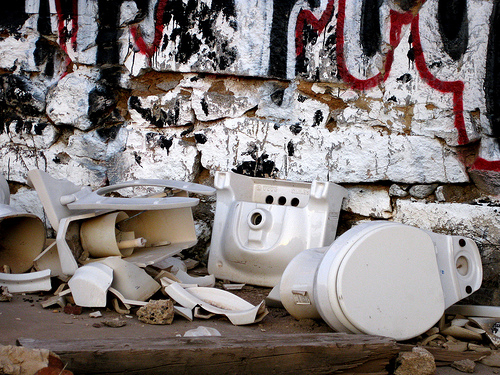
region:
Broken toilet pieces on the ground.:
[61, 253, 273, 338]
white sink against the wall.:
[209, 165, 346, 288]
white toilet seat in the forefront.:
[60, 170, 213, 213]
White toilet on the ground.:
[278, 218, 490, 345]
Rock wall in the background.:
[0, 0, 495, 298]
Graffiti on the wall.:
[31, 0, 498, 177]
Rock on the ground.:
[394, 342, 439, 374]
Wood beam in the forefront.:
[15, 331, 402, 373]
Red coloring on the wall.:
[55, 0, 498, 175]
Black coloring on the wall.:
[32, 2, 497, 182]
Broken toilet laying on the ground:
[25, 137, 239, 311]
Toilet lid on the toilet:
[331, 229, 453, 354]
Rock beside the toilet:
[130, 287, 188, 347]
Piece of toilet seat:
[174, 268, 248, 325]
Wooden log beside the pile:
[40, 320, 298, 364]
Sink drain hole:
[250, 203, 267, 230]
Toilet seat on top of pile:
[67, 165, 237, 240]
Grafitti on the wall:
[300, 20, 477, 117]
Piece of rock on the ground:
[101, 310, 139, 347]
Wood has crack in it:
[260, 340, 315, 370]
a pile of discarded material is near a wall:
[5, 136, 495, 366]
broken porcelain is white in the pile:
[3, 163, 259, 343]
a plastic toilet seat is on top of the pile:
[69, 174, 213, 211]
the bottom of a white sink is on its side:
[208, 170, 333, 295]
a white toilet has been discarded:
[278, 220, 482, 342]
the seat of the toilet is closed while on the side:
[326, 222, 450, 343]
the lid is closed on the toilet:
[335, 224, 447, 343]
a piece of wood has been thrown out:
[13, 329, 404, 374]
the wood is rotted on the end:
[323, 330, 409, 374]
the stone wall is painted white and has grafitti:
[7, 7, 496, 244]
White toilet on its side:
[283, 222, 483, 339]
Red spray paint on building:
[385, 8, 422, 73]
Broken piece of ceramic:
[67, 258, 116, 308]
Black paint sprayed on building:
[267, 0, 292, 85]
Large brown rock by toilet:
[396, 348, 436, 373]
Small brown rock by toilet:
[450, 356, 476, 373]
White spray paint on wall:
[346, 130, 461, 178]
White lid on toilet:
[334, 224, 445, 335]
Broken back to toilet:
[57, 210, 193, 262]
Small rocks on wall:
[387, 182, 447, 199]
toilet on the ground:
[273, 210, 483, 346]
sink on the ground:
[187, 160, 358, 297]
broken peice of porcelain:
[174, 318, 227, 345]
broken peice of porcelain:
[157, 270, 277, 330]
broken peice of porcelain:
[170, 263, 215, 286]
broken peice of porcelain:
[67, 256, 117, 310]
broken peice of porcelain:
[0, 262, 60, 290]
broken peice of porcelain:
[45, 173, 212, 275]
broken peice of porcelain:
[96, 244, 156, 309]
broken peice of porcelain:
[65, 170, 215, 213]